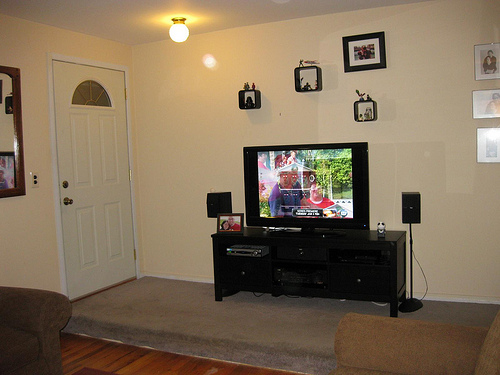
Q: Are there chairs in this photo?
A: Yes, there is a chair.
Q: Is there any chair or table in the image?
A: Yes, there is a chair.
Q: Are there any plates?
A: No, there are no plates.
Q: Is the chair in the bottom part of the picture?
A: Yes, the chair is in the bottom of the image.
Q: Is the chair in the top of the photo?
A: No, the chair is in the bottom of the image.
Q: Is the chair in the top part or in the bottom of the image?
A: The chair is in the bottom of the image.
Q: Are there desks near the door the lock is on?
A: No, there is a chair near the door.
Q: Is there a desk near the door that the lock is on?
A: No, there is a chair near the door.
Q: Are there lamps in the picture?
A: No, there are no lamps.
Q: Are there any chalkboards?
A: No, there are no chalkboards.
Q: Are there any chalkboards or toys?
A: No, there are no chalkboards or toys.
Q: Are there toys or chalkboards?
A: No, there are no chalkboards or toys.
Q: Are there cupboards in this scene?
A: No, there are no cupboards.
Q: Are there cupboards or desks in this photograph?
A: No, there are no cupboards or desks.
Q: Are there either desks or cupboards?
A: No, there are no cupboards or desks.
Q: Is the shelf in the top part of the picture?
A: Yes, the shelf is in the top of the image.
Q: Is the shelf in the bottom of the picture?
A: No, the shelf is in the top of the image.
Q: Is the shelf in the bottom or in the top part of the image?
A: The shelf is in the top of the image.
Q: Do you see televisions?
A: Yes, there is a television.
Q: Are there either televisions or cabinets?
A: Yes, there is a television.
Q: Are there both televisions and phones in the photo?
A: No, there is a television but no phones.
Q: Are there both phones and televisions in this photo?
A: No, there is a television but no phones.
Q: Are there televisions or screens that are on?
A: Yes, the television is on.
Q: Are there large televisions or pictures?
A: Yes, there is a large television.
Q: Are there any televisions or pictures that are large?
A: Yes, the television is large.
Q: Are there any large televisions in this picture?
A: Yes, there is a large television.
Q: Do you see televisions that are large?
A: Yes, there is a large television.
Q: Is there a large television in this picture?
A: Yes, there is a large television.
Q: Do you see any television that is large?
A: Yes, there is a television that is large.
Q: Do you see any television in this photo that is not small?
A: Yes, there is a large television.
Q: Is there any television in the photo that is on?
A: Yes, there is a television that is on.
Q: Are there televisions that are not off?
A: Yes, there is a television that is on.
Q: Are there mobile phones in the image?
A: No, there are no mobile phones.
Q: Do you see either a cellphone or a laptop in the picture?
A: No, there are no cell phones or laptops.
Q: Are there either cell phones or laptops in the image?
A: No, there are no cell phones or laptops.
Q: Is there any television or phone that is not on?
A: No, there is a television but it is on.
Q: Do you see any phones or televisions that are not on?
A: No, there is a television but it is on.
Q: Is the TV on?
A: Yes, the TV is on.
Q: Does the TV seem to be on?
A: Yes, the TV is on.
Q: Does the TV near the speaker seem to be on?
A: Yes, the television is on.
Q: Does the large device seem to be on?
A: Yes, the television is on.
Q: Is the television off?
A: No, the television is on.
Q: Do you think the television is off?
A: No, the television is on.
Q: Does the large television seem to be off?
A: No, the TV is on.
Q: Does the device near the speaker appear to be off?
A: No, the TV is on.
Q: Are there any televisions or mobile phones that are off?
A: No, there is a television but it is on.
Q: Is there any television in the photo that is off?
A: No, there is a television but it is on.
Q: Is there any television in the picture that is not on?
A: No, there is a television but it is on.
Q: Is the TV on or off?
A: The TV is on.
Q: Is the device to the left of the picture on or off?
A: The TV is on.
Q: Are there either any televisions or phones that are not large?
A: No, there is a television but it is large.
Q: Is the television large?
A: Yes, the television is large.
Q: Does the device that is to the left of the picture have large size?
A: Yes, the television is large.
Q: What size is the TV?
A: The TV is large.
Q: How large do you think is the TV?
A: The TV is large.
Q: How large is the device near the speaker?
A: The TV is large.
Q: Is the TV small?
A: No, the TV is large.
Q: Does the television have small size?
A: No, the television is large.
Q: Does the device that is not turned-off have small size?
A: No, the television is large.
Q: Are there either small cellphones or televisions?
A: No, there is a television but it is large.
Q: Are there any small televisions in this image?
A: No, there is a television but it is large.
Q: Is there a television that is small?
A: No, there is a television but it is large.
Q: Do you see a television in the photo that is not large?
A: No, there is a television but it is large.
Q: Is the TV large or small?
A: The TV is large.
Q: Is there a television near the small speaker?
A: Yes, there is a television near the speaker.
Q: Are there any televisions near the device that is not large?
A: Yes, there is a television near the speaker.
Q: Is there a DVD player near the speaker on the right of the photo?
A: No, there is a television near the speaker.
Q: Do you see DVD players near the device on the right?
A: No, there is a television near the speaker.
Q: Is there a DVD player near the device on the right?
A: No, there is a television near the speaker.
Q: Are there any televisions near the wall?
A: Yes, there is a television near the wall.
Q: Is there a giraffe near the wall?
A: No, there is a television near the wall.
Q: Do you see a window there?
A: Yes, there is a window.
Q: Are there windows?
A: Yes, there is a window.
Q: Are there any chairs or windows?
A: Yes, there is a window.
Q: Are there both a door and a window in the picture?
A: Yes, there are both a window and a door.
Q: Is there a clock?
A: No, there are no clocks.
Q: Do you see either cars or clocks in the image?
A: No, there are no clocks or cars.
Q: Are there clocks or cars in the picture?
A: No, there are no clocks or cars.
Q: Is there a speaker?
A: Yes, there is a speaker.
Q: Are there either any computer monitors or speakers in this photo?
A: Yes, there is a speaker.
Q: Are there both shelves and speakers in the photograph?
A: Yes, there are both a speaker and a shelf.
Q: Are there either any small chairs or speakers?
A: Yes, there is a small speaker.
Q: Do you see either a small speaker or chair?
A: Yes, there is a small speaker.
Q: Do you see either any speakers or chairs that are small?
A: Yes, the speaker is small.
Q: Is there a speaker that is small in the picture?
A: Yes, there is a small speaker.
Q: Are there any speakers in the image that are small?
A: Yes, there is a speaker that is small.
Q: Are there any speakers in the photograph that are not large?
A: Yes, there is a small speaker.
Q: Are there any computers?
A: No, there are no computers.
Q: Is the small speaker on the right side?
A: Yes, the speaker is on the right of the image.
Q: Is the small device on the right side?
A: Yes, the speaker is on the right of the image.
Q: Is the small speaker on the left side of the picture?
A: No, the speaker is on the right of the image.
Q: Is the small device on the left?
A: No, the speaker is on the right of the image.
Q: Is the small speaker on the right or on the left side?
A: The speaker is on the right of the image.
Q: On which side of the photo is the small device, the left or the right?
A: The speaker is on the right of the image.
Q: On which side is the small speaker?
A: The speaker is on the right of the image.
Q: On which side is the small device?
A: The speaker is on the right of the image.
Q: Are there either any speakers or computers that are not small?
A: No, there is a speaker but it is small.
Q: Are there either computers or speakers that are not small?
A: No, there is a speaker but it is small.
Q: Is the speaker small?
A: Yes, the speaker is small.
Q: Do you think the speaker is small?
A: Yes, the speaker is small.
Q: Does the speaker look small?
A: Yes, the speaker is small.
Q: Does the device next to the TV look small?
A: Yes, the speaker is small.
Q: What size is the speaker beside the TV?
A: The speaker is small.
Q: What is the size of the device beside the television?
A: The speaker is small.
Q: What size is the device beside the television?
A: The speaker is small.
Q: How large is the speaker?
A: The speaker is small.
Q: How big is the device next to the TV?
A: The speaker is small.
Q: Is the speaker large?
A: No, the speaker is small.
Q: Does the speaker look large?
A: No, the speaker is small.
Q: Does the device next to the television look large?
A: No, the speaker is small.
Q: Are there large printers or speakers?
A: No, there is a speaker but it is small.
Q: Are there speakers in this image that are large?
A: No, there is a speaker but it is small.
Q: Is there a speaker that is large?
A: No, there is a speaker but it is small.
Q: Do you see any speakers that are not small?
A: No, there is a speaker but it is small.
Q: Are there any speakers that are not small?
A: No, there is a speaker but it is small.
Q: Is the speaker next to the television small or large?
A: The speaker is small.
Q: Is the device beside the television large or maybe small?
A: The speaker is small.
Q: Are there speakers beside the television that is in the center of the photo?
A: Yes, there is a speaker beside the TV.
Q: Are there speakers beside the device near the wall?
A: Yes, there is a speaker beside the TV.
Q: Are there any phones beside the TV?
A: No, there is a speaker beside the TV.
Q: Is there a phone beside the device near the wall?
A: No, there is a speaker beside the TV.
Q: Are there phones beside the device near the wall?
A: No, there is a speaker beside the TV.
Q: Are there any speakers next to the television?
A: Yes, there is a speaker next to the television.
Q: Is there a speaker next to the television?
A: Yes, there is a speaker next to the television.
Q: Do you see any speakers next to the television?
A: Yes, there is a speaker next to the television.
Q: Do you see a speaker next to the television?
A: Yes, there is a speaker next to the television.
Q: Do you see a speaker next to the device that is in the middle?
A: Yes, there is a speaker next to the television.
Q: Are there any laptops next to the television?
A: No, there is a speaker next to the television.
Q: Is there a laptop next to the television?
A: No, there is a speaker next to the television.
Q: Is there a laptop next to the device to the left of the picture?
A: No, there is a speaker next to the television.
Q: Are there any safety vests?
A: No, there are no safety vests.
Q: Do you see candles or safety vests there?
A: No, there are no safety vests or candles.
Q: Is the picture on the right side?
A: Yes, the picture is on the right of the image.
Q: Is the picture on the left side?
A: No, the picture is on the right of the image.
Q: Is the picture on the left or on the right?
A: The picture is on the right of the image.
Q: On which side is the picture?
A: The picture is on the right of the image.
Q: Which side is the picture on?
A: The picture is on the right of the image.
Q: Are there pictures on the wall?
A: Yes, there is a picture on the wall.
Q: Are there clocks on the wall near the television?
A: No, there is a picture on the wall.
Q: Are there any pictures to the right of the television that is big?
A: Yes, there is a picture to the right of the television.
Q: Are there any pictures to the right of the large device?
A: Yes, there is a picture to the right of the television.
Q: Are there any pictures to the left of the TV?
A: No, the picture is to the right of the TV.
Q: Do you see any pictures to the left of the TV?
A: No, the picture is to the right of the TV.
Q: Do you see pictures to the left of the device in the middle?
A: No, the picture is to the right of the TV.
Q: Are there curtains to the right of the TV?
A: No, there is a picture to the right of the TV.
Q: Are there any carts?
A: No, there are no carts.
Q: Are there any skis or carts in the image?
A: No, there are no carts or skis.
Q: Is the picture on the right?
A: Yes, the picture is on the right of the image.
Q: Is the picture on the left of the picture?
A: No, the picture is on the right of the image.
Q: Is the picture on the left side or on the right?
A: The picture is on the right of the image.